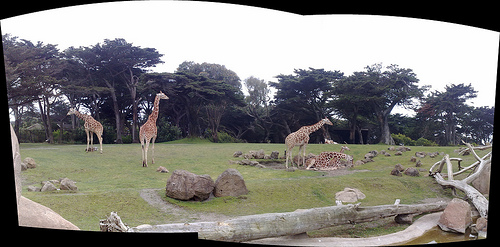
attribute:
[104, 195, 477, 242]
trunk — large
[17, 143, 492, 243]
field — green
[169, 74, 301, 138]
tree — gray, dead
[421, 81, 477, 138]
tree — green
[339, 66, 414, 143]
tree — green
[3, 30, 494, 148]
trees — green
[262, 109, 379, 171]
giraffe — one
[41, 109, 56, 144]
trunk — brown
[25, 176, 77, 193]
rocks — small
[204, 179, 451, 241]
log — grey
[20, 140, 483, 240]
grass — green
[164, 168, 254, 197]
rocks — two and large